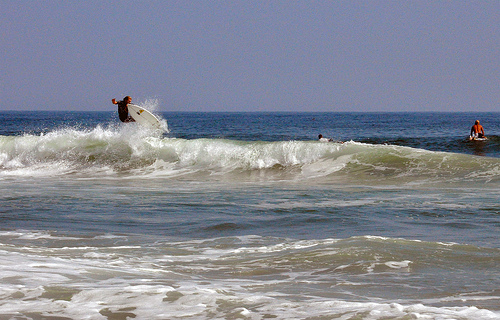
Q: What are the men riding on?
A: Surfboards.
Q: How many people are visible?
A: Three.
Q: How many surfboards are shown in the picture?
A: Two.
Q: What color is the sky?
A: Blue.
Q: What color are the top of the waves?
A: White.